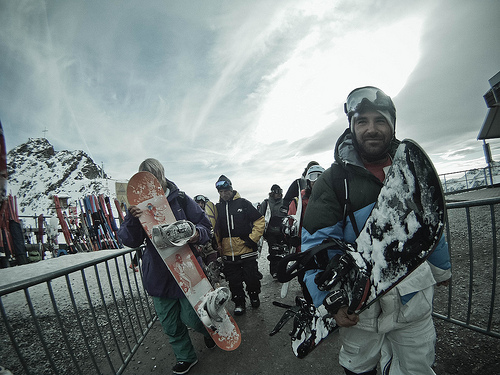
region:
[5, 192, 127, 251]
snowboards along a fence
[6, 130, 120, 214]
a mountain behind the fence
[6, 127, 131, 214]
the mountain is snow-covered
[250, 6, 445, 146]
a break in the clouds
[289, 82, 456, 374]
a man carrying a snowboard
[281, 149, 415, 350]
snow under the snowboard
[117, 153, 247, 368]
a woman carrying a snowboard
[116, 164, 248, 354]
this snowboard is orange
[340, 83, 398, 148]
he is wearing a snowhat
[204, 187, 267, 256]
his jacket is black and yellow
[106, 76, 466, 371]
several people carrying snowboards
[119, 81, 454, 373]
several people walking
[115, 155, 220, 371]
a person holding a snowboard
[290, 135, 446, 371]
a snowboard covered in snow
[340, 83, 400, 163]
a man with a beard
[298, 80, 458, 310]
a man wearing a blue and black jacket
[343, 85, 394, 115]
a pair of snow goggles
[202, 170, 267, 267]
a man wearing a yellow and black jacket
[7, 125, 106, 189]
a snowy mountaintop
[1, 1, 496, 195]
clouds in daytime sky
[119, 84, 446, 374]
people walking with snowboards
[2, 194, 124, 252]
row of leaning skis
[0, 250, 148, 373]
metal rails on fence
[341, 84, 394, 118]
goggles on man's head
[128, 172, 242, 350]
snowboard top covering face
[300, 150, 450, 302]
black and blue coat on man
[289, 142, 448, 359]
snow on board surface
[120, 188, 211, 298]
purple coat on woman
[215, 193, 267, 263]
black and yellow jacket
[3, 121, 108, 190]
A view of mountain tops.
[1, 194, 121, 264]
Skies with the bottom of a mountain in the background.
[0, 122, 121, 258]
Skies in front of a mountain.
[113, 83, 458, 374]
Seven snowboarders walking.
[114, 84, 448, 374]
Seven snowboarders walking with their snowboards.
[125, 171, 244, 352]
A pink snowboard.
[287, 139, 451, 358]
A black snowboard.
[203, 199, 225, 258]
A yellow snowboard.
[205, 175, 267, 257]
A yellow snowboard jacket and snowboard.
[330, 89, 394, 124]
A pair of ski goggles.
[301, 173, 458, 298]
the jacket is black and blue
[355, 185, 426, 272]
snow is on the surfboard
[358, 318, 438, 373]
the pants are white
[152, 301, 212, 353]
the pants are green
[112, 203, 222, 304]
the jacket is purple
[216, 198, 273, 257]
the jacket is blue and purple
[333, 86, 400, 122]
snow goggles are on the forehead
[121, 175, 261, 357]
the snowboard is red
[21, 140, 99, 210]
snow is on the hill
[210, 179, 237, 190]
snow goggles are on the head